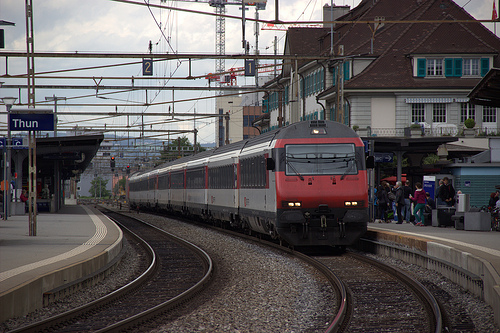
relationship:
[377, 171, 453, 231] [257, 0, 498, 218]
people by building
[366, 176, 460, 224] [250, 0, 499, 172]
people outside a building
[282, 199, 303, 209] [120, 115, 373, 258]
light on train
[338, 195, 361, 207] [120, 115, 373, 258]
light on train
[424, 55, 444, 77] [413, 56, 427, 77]
window with shutters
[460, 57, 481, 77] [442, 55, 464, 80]
window with shutters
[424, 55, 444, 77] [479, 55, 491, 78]
window with shutters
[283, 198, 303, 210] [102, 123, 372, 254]
headlight belonging to train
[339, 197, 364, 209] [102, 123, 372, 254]
headlight belonging to train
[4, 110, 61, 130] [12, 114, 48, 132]
sign displaying word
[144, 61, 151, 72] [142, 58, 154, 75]
2 on sign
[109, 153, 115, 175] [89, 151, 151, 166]
traffic light on a post